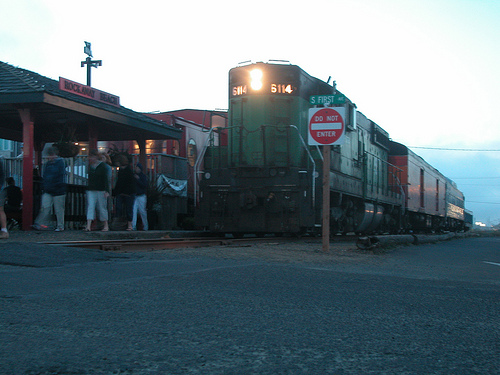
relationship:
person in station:
[132, 162, 147, 228] [0, 61, 182, 237]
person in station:
[86, 153, 112, 231] [0, 61, 182, 237]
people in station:
[29, 145, 69, 232] [0, 61, 182, 237]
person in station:
[4, 174, 26, 234] [0, 61, 182, 237]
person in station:
[110, 153, 136, 234] [0, 61, 182, 237]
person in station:
[1, 162, 10, 242] [0, 61, 182, 237]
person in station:
[15, 141, 27, 166] [0, 61, 182, 237]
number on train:
[230, 81, 249, 98] [197, 57, 476, 245]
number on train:
[268, 81, 294, 96] [197, 57, 476, 245]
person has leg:
[132, 162, 147, 228] [137, 193, 151, 231]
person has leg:
[132, 162, 147, 228] [129, 195, 141, 231]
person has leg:
[110, 153, 136, 234] [125, 192, 135, 230]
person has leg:
[110, 153, 136, 234] [113, 193, 123, 231]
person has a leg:
[86, 153, 112, 231] [84, 191, 95, 232]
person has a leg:
[86, 153, 112, 231] [95, 190, 115, 235]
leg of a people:
[52, 193, 68, 234] [29, 145, 69, 232]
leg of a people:
[34, 191, 51, 232] [29, 145, 69, 232]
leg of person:
[0, 191, 10, 240] [1, 162, 10, 242]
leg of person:
[10, 205, 24, 228] [4, 174, 26, 234]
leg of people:
[52, 193, 68, 234] [29, 145, 69, 232]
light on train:
[243, 65, 269, 96] [197, 57, 476, 245]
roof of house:
[0, 61, 184, 142] [1, 59, 189, 241]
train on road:
[197, 57, 476, 245] [1, 225, 499, 375]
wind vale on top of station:
[78, 40, 104, 93] [0, 61, 182, 237]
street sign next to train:
[306, 92, 345, 257] [197, 57, 476, 245]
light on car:
[243, 65, 269, 96] [188, 57, 407, 255]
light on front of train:
[243, 65, 269, 96] [197, 57, 476, 245]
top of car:
[221, 52, 392, 148] [188, 57, 407, 255]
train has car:
[197, 57, 476, 245] [188, 57, 407, 255]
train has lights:
[197, 57, 476, 245] [245, 63, 269, 94]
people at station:
[3, 139, 156, 236] [0, 61, 182, 237]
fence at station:
[3, 153, 194, 230] [0, 61, 182, 237]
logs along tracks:
[349, 227, 499, 252] [37, 232, 355, 253]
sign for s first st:
[305, 92, 346, 106] [310, 95, 345, 105]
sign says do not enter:
[306, 104, 348, 146] [313, 112, 339, 141]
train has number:
[197, 57, 476, 245] [230, 81, 249, 98]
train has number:
[197, 57, 476, 245] [268, 81, 294, 96]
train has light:
[197, 57, 476, 245] [243, 65, 269, 96]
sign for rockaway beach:
[57, 73, 123, 111] [61, 80, 121, 106]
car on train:
[387, 138, 450, 236] [197, 57, 476, 245]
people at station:
[29, 145, 69, 232] [0, 61, 182, 237]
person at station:
[86, 153, 112, 231] [0, 61, 182, 237]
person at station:
[132, 162, 147, 228] [0, 61, 182, 237]